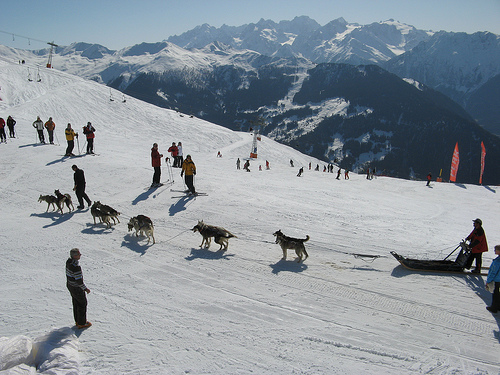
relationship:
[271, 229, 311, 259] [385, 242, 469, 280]
animals pulling a sled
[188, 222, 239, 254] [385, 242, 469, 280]
animals pulling a sled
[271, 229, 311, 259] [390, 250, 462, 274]
animals pulling a sled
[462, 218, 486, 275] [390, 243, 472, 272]
man riding a sled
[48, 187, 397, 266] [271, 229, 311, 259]
ropes connecting animals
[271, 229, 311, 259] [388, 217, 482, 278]
animals on a dog sled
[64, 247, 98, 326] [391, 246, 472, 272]
person watching sled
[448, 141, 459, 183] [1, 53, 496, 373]
flag on slope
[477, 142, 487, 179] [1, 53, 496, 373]
flag on slope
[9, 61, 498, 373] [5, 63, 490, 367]
snow covering ground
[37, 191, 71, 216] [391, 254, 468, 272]
animals are pulling sled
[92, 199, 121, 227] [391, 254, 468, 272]
animals are pulling sled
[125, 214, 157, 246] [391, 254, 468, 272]
animals are pulling sled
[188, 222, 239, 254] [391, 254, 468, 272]
animals are pulling sled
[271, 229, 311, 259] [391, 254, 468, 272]
animals are pulling sled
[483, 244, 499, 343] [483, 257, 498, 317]
person wearing jacket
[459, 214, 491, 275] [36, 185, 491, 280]
person driving dog sled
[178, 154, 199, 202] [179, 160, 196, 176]
people wearing jacket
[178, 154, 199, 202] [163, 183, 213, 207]
people standing on skis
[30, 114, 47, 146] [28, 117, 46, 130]
person wearing top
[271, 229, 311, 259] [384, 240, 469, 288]
animals pulling a sled